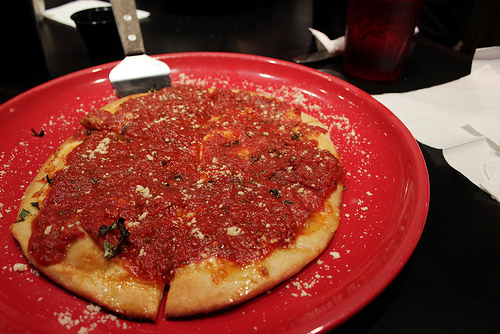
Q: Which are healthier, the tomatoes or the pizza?
A: The tomatoes are healthier than the pizza.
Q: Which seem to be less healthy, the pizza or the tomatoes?
A: The pizza are less healthy than the tomatoes.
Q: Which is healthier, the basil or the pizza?
A: The basil is healthier than the pizza.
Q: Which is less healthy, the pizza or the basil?
A: The pizza is less healthy than the basil.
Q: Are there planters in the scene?
A: No, there are no planters.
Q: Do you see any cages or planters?
A: No, there are no planters or cages.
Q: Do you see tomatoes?
A: Yes, there are tomatoes.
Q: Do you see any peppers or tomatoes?
A: Yes, there are tomatoes.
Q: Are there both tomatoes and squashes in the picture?
A: No, there are tomatoes but no squashes.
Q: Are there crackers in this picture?
A: No, there are no crackers.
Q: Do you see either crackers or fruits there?
A: No, there are no crackers or fruits.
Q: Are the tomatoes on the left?
A: Yes, the tomatoes are on the left of the image.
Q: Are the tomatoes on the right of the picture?
A: No, the tomatoes are on the left of the image.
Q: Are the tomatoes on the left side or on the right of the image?
A: The tomatoes are on the left of the image.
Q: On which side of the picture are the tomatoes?
A: The tomatoes are on the left of the image.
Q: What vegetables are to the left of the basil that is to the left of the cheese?
A: The vegetables are tomatoes.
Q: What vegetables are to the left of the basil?
A: The vegetables are tomatoes.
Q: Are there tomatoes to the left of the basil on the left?
A: Yes, there are tomatoes to the left of the basil.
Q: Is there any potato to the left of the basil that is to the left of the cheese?
A: No, there are tomatoes to the left of the basil.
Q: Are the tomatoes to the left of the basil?
A: Yes, the tomatoes are to the left of the basil.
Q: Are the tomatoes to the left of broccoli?
A: No, the tomatoes are to the left of the basil.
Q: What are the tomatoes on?
A: The tomatoes are on the crust.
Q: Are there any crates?
A: No, there are no crates.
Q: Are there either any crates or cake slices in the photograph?
A: No, there are no crates or cake slices.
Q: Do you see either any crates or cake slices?
A: No, there are no crates or cake slices.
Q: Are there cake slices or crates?
A: No, there are no crates or cake slices.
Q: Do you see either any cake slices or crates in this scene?
A: No, there are no crates or cake slices.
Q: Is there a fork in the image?
A: No, there are no forks.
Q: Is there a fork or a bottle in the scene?
A: No, there are no forks or bottles.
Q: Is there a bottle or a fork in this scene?
A: No, there are no forks or bottles.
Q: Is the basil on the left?
A: Yes, the basil is on the left of the image.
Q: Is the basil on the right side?
A: No, the basil is on the left of the image.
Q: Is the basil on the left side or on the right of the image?
A: The basil is on the left of the image.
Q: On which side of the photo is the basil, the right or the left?
A: The basil is on the left of the image.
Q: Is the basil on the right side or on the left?
A: The basil is on the left of the image.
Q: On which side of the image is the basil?
A: The basil is on the left of the image.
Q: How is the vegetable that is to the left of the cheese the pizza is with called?
A: The vegetable is basil.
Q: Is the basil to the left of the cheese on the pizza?
A: Yes, the basil is to the left of the cheese.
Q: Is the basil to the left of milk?
A: No, the basil is to the left of the cheese.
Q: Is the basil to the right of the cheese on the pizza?
A: No, the basil is to the left of the cheese.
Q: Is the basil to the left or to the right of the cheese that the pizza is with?
A: The basil is to the left of the cheese.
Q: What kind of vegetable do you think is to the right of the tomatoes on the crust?
A: The vegetable is basil.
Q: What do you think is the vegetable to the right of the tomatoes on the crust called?
A: The vegetable is basil.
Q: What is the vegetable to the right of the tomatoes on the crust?
A: The vegetable is basil.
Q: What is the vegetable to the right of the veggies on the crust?
A: The vegetable is basil.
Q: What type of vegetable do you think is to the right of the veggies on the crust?
A: The vegetable is basil.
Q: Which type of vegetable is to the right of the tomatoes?
A: The vegetable is basil.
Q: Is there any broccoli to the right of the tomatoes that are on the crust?
A: No, there is basil to the right of the tomatoes.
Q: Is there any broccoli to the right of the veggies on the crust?
A: No, there is basil to the right of the tomatoes.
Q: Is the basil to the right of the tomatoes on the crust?
A: Yes, the basil is to the right of the tomatoes.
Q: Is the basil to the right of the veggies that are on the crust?
A: Yes, the basil is to the right of the tomatoes.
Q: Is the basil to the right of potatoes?
A: No, the basil is to the right of the tomatoes.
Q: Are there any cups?
A: Yes, there is a cup.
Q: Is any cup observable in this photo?
A: Yes, there is a cup.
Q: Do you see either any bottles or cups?
A: Yes, there is a cup.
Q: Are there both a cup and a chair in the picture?
A: No, there is a cup but no chairs.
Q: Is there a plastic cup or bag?
A: Yes, there is a plastic cup.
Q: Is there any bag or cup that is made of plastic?
A: Yes, the cup is made of plastic.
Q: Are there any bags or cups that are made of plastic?
A: Yes, the cup is made of plastic.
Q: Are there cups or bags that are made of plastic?
A: Yes, the cup is made of plastic.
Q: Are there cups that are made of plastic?
A: Yes, there is a cup that is made of plastic.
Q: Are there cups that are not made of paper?
A: Yes, there is a cup that is made of plastic.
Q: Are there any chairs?
A: No, there are no chairs.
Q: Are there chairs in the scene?
A: No, there are no chairs.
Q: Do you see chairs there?
A: No, there are no chairs.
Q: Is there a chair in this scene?
A: No, there are no chairs.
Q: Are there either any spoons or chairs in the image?
A: No, there are no chairs or spoons.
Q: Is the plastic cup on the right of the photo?
A: Yes, the cup is on the right of the image.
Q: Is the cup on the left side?
A: No, the cup is on the right of the image.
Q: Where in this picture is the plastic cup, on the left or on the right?
A: The cup is on the right of the image.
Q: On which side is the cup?
A: The cup is on the right of the image.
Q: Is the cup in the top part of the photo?
A: Yes, the cup is in the top of the image.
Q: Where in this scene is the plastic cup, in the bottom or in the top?
A: The cup is in the top of the image.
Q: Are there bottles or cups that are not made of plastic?
A: No, there is a cup but it is made of plastic.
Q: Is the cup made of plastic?
A: Yes, the cup is made of plastic.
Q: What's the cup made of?
A: The cup is made of plastic.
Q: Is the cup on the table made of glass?
A: No, the cup is made of plastic.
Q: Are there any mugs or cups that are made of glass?
A: No, there is a cup but it is made of plastic.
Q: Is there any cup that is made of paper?
A: No, there is a cup but it is made of plastic.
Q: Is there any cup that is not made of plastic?
A: No, there is a cup but it is made of plastic.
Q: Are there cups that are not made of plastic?
A: No, there is a cup but it is made of plastic.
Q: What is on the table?
A: The cup is on the table.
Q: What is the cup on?
A: The cup is on the table.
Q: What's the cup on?
A: The cup is on the table.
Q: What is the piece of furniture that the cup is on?
A: The piece of furniture is a table.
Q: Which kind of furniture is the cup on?
A: The cup is on the table.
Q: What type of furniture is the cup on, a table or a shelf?
A: The cup is on a table.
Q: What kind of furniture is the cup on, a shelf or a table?
A: The cup is on a table.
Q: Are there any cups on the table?
A: Yes, there is a cup on the table.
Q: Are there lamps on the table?
A: No, there is a cup on the table.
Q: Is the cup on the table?
A: Yes, the cup is on the table.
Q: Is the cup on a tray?
A: No, the cup is on the table.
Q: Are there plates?
A: Yes, there is a plate.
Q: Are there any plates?
A: Yes, there is a plate.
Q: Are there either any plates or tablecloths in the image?
A: Yes, there is a plate.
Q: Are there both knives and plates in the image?
A: No, there is a plate but no knives.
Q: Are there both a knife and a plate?
A: No, there is a plate but no knives.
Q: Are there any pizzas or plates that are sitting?
A: Yes, the plate is sitting.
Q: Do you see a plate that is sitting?
A: Yes, there is a plate that is sitting.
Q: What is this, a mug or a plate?
A: This is a plate.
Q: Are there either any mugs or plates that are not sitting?
A: No, there is a plate but it is sitting.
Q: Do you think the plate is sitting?
A: Yes, the plate is sitting.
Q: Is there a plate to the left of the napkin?
A: Yes, there is a plate to the left of the napkin.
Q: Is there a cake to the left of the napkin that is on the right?
A: No, there is a plate to the left of the napkin.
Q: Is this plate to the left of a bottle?
A: No, the plate is to the left of the napkin.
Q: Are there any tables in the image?
A: Yes, there is a table.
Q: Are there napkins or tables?
A: Yes, there is a table.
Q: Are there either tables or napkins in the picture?
A: Yes, there is a table.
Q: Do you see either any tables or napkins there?
A: Yes, there is a table.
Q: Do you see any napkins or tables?
A: Yes, there is a table.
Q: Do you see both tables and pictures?
A: No, there is a table but no pictures.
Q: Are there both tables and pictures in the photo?
A: No, there is a table but no pictures.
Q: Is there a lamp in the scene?
A: No, there are no lamps.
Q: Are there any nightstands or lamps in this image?
A: No, there are no lamps or nightstands.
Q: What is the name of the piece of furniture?
A: The piece of furniture is a table.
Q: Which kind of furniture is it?
A: The piece of furniture is a table.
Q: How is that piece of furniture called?
A: That is a table.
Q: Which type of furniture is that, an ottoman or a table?
A: That is a table.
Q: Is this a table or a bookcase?
A: This is a table.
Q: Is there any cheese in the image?
A: Yes, there is cheese.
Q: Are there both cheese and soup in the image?
A: No, there is cheese but no soup.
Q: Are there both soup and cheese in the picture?
A: No, there is cheese but no soup.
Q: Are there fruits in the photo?
A: No, there are no fruits.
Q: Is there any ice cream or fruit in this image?
A: No, there are no fruits or ice cream.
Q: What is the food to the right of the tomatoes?
A: The food is cheese.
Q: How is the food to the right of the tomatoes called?
A: The food is cheese.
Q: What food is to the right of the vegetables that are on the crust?
A: The food is cheese.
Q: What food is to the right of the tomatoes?
A: The food is cheese.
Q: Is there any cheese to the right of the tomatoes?
A: Yes, there is cheese to the right of the tomatoes.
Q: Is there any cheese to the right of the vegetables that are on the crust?
A: Yes, there is cheese to the right of the tomatoes.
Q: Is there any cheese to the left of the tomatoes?
A: No, the cheese is to the right of the tomatoes.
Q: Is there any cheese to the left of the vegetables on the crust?
A: No, the cheese is to the right of the tomatoes.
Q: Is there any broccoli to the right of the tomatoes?
A: No, there is cheese to the right of the tomatoes.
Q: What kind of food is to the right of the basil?
A: The food is cheese.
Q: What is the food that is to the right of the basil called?
A: The food is cheese.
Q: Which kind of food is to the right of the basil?
A: The food is cheese.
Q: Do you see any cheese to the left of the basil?
A: No, the cheese is to the right of the basil.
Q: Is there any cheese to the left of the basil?
A: No, the cheese is to the right of the basil.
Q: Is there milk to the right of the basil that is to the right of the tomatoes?
A: No, there is cheese to the right of the basil.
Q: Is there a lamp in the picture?
A: No, there are no lamps.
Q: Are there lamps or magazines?
A: No, there are no lamps or magazines.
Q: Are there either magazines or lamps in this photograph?
A: No, there are no lamps or magazines.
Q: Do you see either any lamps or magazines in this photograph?
A: No, there are no lamps or magazines.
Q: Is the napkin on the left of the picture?
A: No, the napkin is on the right of the image.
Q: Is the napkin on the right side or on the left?
A: The napkin is on the right of the image.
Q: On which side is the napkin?
A: The napkin is on the right of the image.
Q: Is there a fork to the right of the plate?
A: No, there is a napkin to the right of the plate.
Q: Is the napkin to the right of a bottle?
A: No, the napkin is to the right of the plate.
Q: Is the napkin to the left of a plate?
A: No, the napkin is to the right of a plate.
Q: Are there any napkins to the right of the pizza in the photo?
A: Yes, there is a napkin to the right of the pizza.